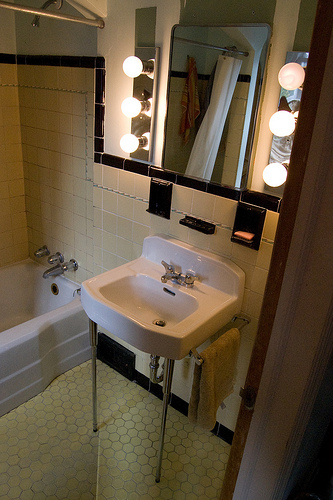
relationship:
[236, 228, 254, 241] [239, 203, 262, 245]
soap on a holder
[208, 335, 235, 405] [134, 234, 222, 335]
towel on side of sink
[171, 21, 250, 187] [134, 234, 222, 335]
mirror over sink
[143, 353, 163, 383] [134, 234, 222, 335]
pipes under sink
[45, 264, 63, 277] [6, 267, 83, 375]
faucet in bathtub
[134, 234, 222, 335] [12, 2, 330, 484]
sink in bathroom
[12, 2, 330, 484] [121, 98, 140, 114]
bathroom with light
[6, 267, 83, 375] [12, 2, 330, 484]
bathtub in bathroom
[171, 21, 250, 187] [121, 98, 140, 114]
mirror with light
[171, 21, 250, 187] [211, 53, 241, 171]
mirror reflecting curtain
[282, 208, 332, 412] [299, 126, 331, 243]
door made of wood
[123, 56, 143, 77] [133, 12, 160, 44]
lights attached to wall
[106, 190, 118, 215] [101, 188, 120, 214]
tiles on wall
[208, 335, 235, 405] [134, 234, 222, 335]
towel next to sink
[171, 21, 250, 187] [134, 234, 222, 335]
mirror above sink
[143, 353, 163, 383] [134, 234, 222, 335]
metal under sink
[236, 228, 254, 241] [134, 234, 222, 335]
soap above sink